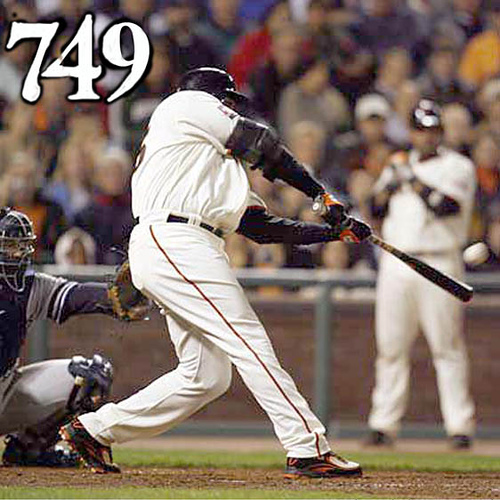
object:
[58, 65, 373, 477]
baseball player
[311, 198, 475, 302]
bat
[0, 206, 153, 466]
catcher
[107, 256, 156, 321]
mitt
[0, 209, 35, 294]
mask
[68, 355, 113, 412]
knee pad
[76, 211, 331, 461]
pants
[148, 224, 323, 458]
stripe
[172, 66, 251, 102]
helmet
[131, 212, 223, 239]
belt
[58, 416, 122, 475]
shoe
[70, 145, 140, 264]
people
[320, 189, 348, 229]
glove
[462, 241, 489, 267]
baseball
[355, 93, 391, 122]
baseball cap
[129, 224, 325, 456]
leg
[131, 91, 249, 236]
shirt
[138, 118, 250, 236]
wrinkles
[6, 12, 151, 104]
749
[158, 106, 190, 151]
white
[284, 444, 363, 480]
shoes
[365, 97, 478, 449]
baseball player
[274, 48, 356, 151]
audience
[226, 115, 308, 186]
elbow pad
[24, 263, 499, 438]
rail